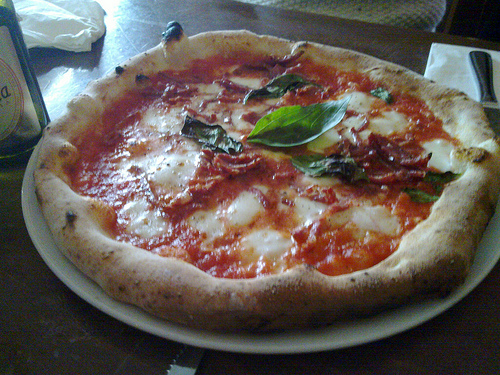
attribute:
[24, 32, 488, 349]
pizza — round, brown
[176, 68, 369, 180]
basil — sprinkled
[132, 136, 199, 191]
white mozzerella — melted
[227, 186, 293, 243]
mozzerella — white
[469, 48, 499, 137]
knife — silver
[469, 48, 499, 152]
utensil — silver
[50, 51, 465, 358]
pizza — pie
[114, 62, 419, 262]
mozzarella — melted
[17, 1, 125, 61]
napkin — crumpled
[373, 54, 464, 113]
criust — burnt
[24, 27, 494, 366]
plate — white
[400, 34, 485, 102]
napkin — white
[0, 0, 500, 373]
table — brown, wooden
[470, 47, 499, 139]
utensil — silver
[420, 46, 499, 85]
napkin — white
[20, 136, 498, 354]
plate — white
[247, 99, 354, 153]
leaf — green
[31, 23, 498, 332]
pizza — whole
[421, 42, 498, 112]
napkin — white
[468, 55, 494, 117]
knife — silver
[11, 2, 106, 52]
napkin — white, crumpled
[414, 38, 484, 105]
napkin — white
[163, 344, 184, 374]
blade — serrated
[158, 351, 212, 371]
knife — silver